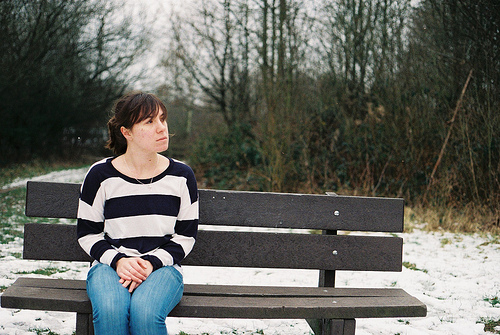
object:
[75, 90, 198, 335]
woman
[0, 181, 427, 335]
bench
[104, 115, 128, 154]
ponytail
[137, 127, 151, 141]
pimples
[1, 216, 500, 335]
field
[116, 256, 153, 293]
hands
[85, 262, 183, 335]
jeans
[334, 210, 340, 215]
bolts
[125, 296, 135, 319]
lap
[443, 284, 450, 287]
snow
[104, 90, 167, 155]
hair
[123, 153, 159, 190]
necklace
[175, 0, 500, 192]
trees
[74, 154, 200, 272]
shirt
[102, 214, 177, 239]
stripes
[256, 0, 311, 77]
branch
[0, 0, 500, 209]
woods